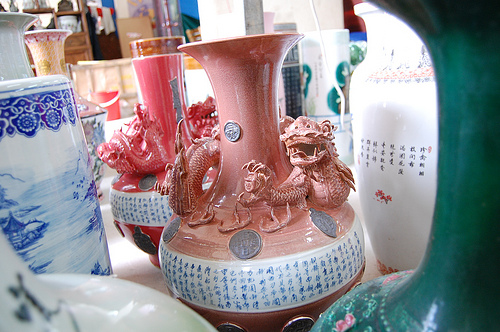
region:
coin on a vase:
[226, 222, 262, 259]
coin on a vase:
[307, 202, 340, 244]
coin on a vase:
[222, 118, 244, 144]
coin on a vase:
[159, 212, 187, 245]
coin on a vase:
[282, 308, 316, 330]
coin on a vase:
[217, 318, 244, 330]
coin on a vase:
[136, 171, 159, 192]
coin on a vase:
[128, 225, 158, 257]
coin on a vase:
[106, 170, 126, 185]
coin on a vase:
[111, 220, 126, 240]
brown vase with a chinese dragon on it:
[155, 19, 373, 326]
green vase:
[306, 1, 497, 329]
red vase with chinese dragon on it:
[94, 45, 226, 272]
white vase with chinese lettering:
[346, 2, 445, 279]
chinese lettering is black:
[352, 134, 433, 178]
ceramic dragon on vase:
[156, 109, 360, 235]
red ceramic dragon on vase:
[97, 92, 222, 192]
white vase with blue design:
[0, 65, 117, 287]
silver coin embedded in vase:
[228, 226, 265, 258]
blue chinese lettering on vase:
[155, 230, 370, 315]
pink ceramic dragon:
[279, 115, 356, 205]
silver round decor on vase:
[230, 228, 260, 259]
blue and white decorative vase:
[0, 74, 112, 272]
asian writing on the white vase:
[359, 136, 432, 178]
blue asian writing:
[161, 233, 366, 304]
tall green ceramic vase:
[309, 0, 494, 330]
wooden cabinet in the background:
[27, 3, 91, 64]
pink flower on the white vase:
[373, 191, 392, 203]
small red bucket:
[96, 90, 121, 117]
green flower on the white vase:
[298, 61, 310, 97]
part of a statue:
[243, 153, 301, 244]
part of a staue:
[252, 160, 312, 241]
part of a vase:
[258, 229, 300, 288]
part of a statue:
[250, 176, 276, 218]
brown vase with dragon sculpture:
[170, 37, 350, 313]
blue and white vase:
[2, 73, 112, 273]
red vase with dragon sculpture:
[109, 55, 221, 282]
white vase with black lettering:
[349, 7, 442, 279]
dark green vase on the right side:
[315, 0, 497, 330]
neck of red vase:
[130, 47, 191, 158]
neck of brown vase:
[182, 23, 294, 186]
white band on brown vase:
[157, 244, 368, 309]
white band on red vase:
[110, 187, 176, 229]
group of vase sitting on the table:
[5, 10, 496, 326]